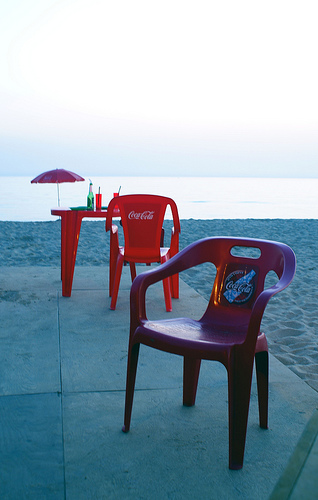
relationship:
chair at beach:
[124, 233, 274, 472] [4, 214, 313, 407]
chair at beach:
[105, 192, 181, 313] [4, 214, 313, 407]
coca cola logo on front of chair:
[220, 259, 257, 309] [124, 233, 274, 472]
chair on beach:
[124, 233, 274, 472] [4, 214, 313, 407]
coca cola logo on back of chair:
[122, 203, 159, 235] [105, 192, 181, 313]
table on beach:
[48, 208, 167, 305] [4, 214, 313, 407]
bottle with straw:
[86, 185, 97, 208] [89, 177, 95, 183]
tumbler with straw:
[91, 193, 101, 216] [96, 186, 102, 192]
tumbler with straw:
[113, 190, 125, 202] [117, 182, 127, 193]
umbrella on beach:
[30, 166, 86, 186] [4, 214, 313, 407]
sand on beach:
[4, 219, 317, 400] [4, 214, 313, 407]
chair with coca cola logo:
[124, 233, 274, 472] [220, 259, 257, 309]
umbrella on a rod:
[30, 166, 86, 186] [56, 180, 64, 215]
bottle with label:
[86, 185, 97, 208] [88, 196, 96, 212]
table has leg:
[48, 208, 167, 305] [63, 218, 75, 302]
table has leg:
[48, 208, 167, 305] [59, 218, 67, 293]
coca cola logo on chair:
[122, 203, 159, 235] [105, 192, 181, 313]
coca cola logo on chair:
[220, 259, 257, 309] [124, 233, 274, 472]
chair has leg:
[124, 233, 274, 472] [124, 340, 136, 435]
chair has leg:
[124, 233, 274, 472] [225, 365, 250, 474]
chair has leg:
[124, 233, 274, 472] [180, 358, 196, 410]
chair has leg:
[124, 233, 274, 472] [255, 361, 270, 432]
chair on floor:
[124, 233, 274, 472] [7, 264, 317, 497]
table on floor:
[48, 208, 167, 305] [7, 264, 317, 497]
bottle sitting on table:
[86, 185, 97, 208] [48, 208, 167, 305]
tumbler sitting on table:
[91, 193, 101, 216] [48, 208, 167, 305]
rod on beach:
[56, 180, 64, 215] [4, 214, 313, 407]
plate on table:
[70, 205, 91, 211] [48, 208, 167, 305]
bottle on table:
[86, 185, 97, 208] [48, 208, 167, 305]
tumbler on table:
[91, 193, 101, 216] [48, 208, 167, 305]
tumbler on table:
[113, 190, 125, 202] [48, 208, 167, 305]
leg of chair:
[124, 340, 136, 435] [124, 233, 274, 472]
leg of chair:
[225, 365, 250, 474] [124, 233, 274, 472]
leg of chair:
[180, 358, 196, 410] [124, 233, 274, 472]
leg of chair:
[255, 361, 270, 432] [124, 233, 274, 472]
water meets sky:
[1, 176, 303, 225] [3, 4, 315, 182]